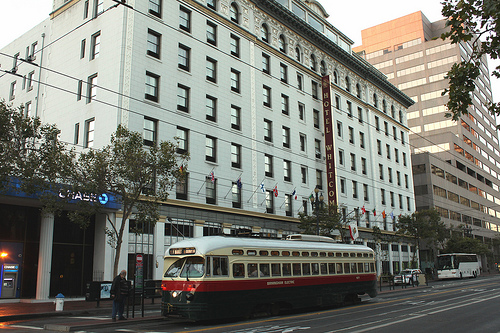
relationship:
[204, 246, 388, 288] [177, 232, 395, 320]
windows on trolley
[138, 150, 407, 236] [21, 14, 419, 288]
flags on building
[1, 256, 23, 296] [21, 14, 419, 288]
atm on building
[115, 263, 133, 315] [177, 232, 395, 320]
man near trolley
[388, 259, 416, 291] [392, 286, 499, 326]
car on road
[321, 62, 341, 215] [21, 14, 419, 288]
sign on building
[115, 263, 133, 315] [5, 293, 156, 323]
man on sidewalk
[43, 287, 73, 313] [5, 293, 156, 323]
hydrant on sidewalk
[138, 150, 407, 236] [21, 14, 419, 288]
flags hanging on building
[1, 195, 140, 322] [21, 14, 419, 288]
bank near building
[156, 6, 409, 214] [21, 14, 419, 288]
windows on building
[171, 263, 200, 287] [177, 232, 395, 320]
wipers on trolley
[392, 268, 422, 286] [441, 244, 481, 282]
car near bus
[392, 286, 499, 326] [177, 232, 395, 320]
road near trolley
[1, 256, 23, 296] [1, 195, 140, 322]
atm near bank